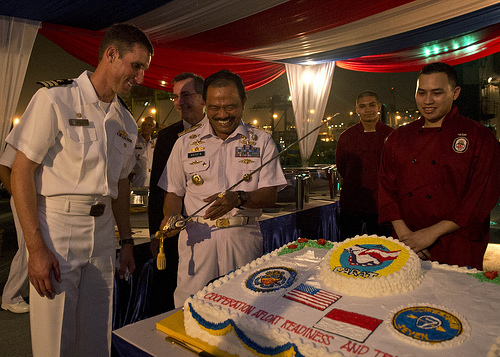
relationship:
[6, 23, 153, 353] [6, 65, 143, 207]
man wearing shirt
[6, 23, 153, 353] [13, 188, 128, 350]
man wearing pants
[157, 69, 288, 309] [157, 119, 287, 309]
man wearing white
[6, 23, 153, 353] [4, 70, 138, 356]
man wearing dress whites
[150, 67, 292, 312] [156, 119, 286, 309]
man wearing indonesian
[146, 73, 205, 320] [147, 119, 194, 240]
man wearing suit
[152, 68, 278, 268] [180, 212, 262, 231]
man wearing belt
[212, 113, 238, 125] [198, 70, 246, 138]
mustache on a face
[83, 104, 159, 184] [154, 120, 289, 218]
button and awards on a shirt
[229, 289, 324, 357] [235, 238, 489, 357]
indonesia flag on cake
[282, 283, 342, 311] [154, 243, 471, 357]
flag flag on cake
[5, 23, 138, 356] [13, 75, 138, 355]
man captain in dress whites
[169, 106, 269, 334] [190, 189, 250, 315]
indonesian navy captain in white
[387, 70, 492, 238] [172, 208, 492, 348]
chef by cake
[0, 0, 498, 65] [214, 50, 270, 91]
fabric on ceiling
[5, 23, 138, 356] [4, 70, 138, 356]
man wearing a white navy dress whites